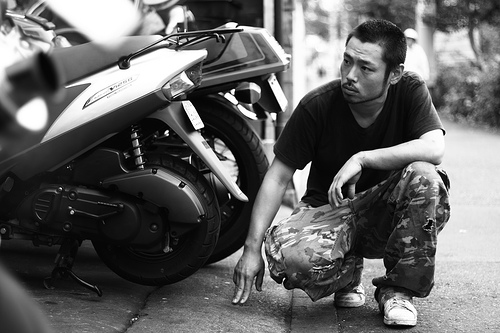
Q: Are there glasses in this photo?
A: No, there are no glasses.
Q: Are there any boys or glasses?
A: No, there are no glasses or boys.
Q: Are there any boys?
A: No, there are no boys.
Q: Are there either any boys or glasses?
A: No, there are no boys or glasses.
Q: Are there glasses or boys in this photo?
A: No, there are no boys or glasses.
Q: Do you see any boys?
A: No, there are no boys.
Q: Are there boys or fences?
A: No, there are no boys or fences.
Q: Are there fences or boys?
A: No, there are no boys or fences.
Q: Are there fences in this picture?
A: No, there are no fences.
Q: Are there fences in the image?
A: No, there are no fences.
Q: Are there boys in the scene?
A: No, there are no boys.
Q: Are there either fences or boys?
A: No, there are no boys or fences.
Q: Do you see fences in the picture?
A: No, there are no fences.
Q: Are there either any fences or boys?
A: No, there are no fences or boys.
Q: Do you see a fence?
A: No, there are no fences.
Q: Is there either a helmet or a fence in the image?
A: No, there are no fences or helmets.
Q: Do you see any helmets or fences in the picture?
A: No, there are no fences or helmets.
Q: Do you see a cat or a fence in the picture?
A: No, there are no fences or cats.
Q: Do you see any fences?
A: No, there are no fences.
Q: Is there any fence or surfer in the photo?
A: No, there are no fences or surfers.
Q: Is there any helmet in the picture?
A: No, there are no helmets.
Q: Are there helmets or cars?
A: No, there are no helmets or cars.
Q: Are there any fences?
A: No, there are no fences.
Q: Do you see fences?
A: No, there are no fences.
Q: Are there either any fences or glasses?
A: No, there are no fences or glasses.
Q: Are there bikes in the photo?
A: Yes, there is a bike.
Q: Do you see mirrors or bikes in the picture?
A: Yes, there is a bike.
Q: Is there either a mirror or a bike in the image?
A: Yes, there is a bike.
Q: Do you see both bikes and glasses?
A: No, there is a bike but no glasses.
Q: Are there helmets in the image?
A: No, there are no helmets.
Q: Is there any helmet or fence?
A: No, there are no helmets or fences.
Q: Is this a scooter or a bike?
A: This is a bike.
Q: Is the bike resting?
A: Yes, the bike is resting.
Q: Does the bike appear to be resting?
A: Yes, the bike is resting.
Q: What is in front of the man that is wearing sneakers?
A: The bike is in front of the man.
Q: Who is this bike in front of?
A: The bike is in front of the man.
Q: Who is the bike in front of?
A: The bike is in front of the man.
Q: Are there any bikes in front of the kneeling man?
A: Yes, there is a bike in front of the man.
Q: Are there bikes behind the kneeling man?
A: No, the bike is in front of the man.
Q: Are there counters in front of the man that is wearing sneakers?
A: No, there is a bike in front of the man.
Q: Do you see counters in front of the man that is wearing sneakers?
A: No, there is a bike in front of the man.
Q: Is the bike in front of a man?
A: Yes, the bike is in front of a man.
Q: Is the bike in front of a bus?
A: No, the bike is in front of a man.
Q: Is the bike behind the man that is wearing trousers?
A: No, the bike is in front of the man.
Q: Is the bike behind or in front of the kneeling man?
A: The bike is in front of the man.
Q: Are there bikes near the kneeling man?
A: Yes, there is a bike near the man.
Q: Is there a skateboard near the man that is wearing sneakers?
A: No, there is a bike near the man.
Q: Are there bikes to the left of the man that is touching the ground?
A: Yes, there is a bike to the left of the man.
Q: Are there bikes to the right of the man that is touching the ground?
A: No, the bike is to the left of the man.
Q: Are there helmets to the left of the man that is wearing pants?
A: No, there is a bike to the left of the man.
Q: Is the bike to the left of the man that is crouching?
A: Yes, the bike is to the left of the man.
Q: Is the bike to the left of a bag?
A: No, the bike is to the left of the man.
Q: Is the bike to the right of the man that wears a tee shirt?
A: No, the bike is to the left of the man.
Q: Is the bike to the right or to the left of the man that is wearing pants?
A: The bike is to the left of the man.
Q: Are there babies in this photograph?
A: No, there are no babies.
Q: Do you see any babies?
A: No, there are no babies.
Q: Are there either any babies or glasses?
A: No, there are no babies or glasses.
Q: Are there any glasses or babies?
A: No, there are no babies or glasses.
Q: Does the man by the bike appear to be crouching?
A: Yes, the man is crouching.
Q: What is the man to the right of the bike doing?
A: The man is crouching.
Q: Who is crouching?
A: The man is crouching.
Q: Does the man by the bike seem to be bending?
A: No, the man is crouching.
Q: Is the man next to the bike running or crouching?
A: The man is crouching.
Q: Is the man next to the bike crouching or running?
A: The man is crouching.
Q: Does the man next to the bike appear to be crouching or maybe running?
A: The man is crouching.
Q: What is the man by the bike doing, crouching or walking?
A: The man is crouching.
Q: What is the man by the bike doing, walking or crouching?
A: The man is crouching.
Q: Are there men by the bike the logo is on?
A: Yes, there is a man by the bike.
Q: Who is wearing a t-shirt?
A: The man is wearing a t-shirt.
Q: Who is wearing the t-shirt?
A: The man is wearing a t-shirt.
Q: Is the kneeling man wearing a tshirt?
A: Yes, the man is wearing a tshirt.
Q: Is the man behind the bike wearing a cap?
A: No, the man is wearing a tshirt.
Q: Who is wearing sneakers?
A: The man is wearing sneakers.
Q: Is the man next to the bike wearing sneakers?
A: Yes, the man is wearing sneakers.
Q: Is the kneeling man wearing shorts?
A: No, the man is wearing sneakers.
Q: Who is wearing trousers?
A: The man is wearing trousers.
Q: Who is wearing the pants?
A: The man is wearing trousers.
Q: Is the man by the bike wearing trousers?
A: Yes, the man is wearing trousers.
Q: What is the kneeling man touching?
A: The man is touching the ground.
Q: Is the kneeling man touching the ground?
A: Yes, the man is touching the ground.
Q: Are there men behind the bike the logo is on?
A: Yes, there is a man behind the bike.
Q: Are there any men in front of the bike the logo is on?
A: No, the man is behind the bike.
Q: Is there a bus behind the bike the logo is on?
A: No, there is a man behind the bike.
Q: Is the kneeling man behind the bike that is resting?
A: Yes, the man is behind the bike.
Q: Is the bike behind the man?
A: No, the man is behind the bike.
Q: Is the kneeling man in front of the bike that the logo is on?
A: No, the man is behind the bike.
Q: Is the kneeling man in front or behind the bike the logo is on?
A: The man is behind the bike.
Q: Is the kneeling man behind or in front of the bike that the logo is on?
A: The man is behind the bike.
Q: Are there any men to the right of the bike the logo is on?
A: Yes, there is a man to the right of the bike.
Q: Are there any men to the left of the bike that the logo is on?
A: No, the man is to the right of the bike.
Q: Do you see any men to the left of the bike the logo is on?
A: No, the man is to the right of the bike.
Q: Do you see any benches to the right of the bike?
A: No, there is a man to the right of the bike.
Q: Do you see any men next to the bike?
A: Yes, there is a man next to the bike.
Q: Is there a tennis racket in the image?
A: No, there are no rackets.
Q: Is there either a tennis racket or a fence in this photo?
A: No, there are no rackets or fences.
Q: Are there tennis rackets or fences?
A: No, there are no tennis rackets or fences.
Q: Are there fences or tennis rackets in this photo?
A: No, there are no tennis rackets or fences.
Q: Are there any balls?
A: No, there are no balls.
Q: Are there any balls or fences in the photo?
A: No, there are no balls or fences.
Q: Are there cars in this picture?
A: No, there are no cars.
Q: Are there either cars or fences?
A: No, there are no cars or fences.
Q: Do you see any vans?
A: No, there are no vans.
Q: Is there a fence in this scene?
A: No, there are no fences.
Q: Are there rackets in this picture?
A: No, there are no rackets.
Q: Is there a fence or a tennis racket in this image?
A: No, there are no rackets or fences.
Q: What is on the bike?
A: The logo is on the bike.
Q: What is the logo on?
A: The logo is on the bike.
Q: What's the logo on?
A: The logo is on the bike.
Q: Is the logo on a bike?
A: Yes, the logo is on a bike.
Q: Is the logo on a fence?
A: No, the logo is on a bike.